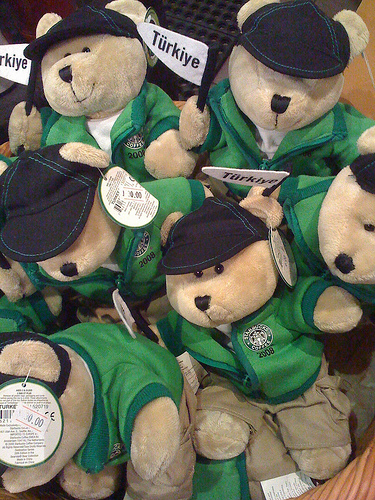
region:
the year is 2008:
[254, 342, 275, 360]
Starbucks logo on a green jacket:
[241, 317, 271, 351]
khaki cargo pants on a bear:
[196, 372, 347, 454]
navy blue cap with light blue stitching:
[155, 194, 266, 275]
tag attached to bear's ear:
[271, 223, 298, 287]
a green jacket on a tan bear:
[159, 271, 344, 400]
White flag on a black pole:
[137, 16, 214, 104]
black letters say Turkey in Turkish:
[151, 24, 199, 69]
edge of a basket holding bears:
[292, 439, 373, 497]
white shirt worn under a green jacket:
[76, 101, 129, 154]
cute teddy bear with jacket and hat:
[0, 326, 192, 495]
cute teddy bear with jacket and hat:
[152, 182, 352, 482]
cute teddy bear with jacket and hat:
[0, 129, 213, 309]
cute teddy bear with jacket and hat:
[243, 126, 369, 302]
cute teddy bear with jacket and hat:
[173, 31, 371, 173]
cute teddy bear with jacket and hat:
[3, 0, 205, 177]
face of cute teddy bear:
[174, 257, 265, 327]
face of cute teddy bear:
[328, 194, 373, 268]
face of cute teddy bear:
[49, 44, 111, 108]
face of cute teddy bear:
[251, 55, 312, 135]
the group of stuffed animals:
[0, 0, 373, 498]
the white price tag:
[10, 401, 50, 436]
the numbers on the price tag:
[11, 401, 50, 435]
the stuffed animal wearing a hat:
[161, 194, 364, 481]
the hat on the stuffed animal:
[137, 193, 362, 481]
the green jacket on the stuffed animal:
[137, 190, 360, 479]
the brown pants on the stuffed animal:
[140, 194, 362, 480]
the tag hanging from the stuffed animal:
[137, 193, 360, 479]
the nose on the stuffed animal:
[141, 196, 363, 479]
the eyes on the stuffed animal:
[142, 197, 363, 479]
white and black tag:
[127, 22, 212, 98]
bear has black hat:
[167, 208, 254, 278]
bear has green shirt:
[203, 279, 313, 404]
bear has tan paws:
[276, 271, 368, 353]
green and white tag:
[118, 170, 152, 235]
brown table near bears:
[287, 418, 362, 493]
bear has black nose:
[242, 59, 285, 108]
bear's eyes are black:
[185, 230, 231, 311]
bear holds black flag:
[163, 15, 240, 105]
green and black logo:
[229, 257, 278, 375]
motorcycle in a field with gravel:
[197, 448, 203, 449]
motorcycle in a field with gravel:
[184, 475, 201, 491]